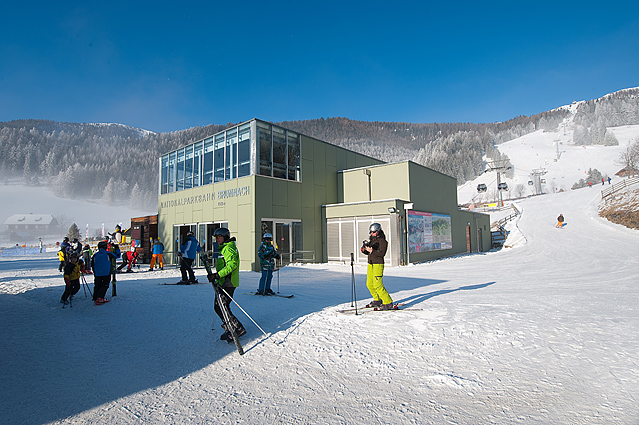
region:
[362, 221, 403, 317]
Person in yellow and black ski gear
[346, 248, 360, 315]
Ski poles stuck in snow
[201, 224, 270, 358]
Person in lime green winter coat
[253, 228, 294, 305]
Person using skis and ski poles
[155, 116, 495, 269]
Light grey ski lodge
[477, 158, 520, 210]
Ski lift in background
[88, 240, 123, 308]
Person in blue jacket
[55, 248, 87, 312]
Person using skis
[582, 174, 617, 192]
Skiiers in background on ski slope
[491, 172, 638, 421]
Long ski slope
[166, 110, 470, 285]
tan building with large windows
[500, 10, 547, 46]
white clouds in blue sky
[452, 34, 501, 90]
white clouds in blue sky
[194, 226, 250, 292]
coat is green in color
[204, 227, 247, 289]
woman is wearing coat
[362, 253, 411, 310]
pants are yellow in color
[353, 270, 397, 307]
person is wearing pants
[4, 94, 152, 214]
trees on the mountain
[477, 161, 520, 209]
ski lift for skiiers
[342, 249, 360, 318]
ski handles for skiier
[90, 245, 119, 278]
coat is blue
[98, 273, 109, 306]
pants are black in color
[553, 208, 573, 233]
person on hill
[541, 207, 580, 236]
A beginner skiing down the bunny slope.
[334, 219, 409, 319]
She is taking a selfie before going skiing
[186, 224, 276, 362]
He is walking towards the ski shop.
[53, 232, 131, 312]
A group of friends getting ready to hit the slope.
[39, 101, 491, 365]
Today ski class is gathering for their class.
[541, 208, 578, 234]
Returning from an early morning ski run.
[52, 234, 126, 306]
The kids are waiting for their parents.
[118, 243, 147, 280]
A beginner about to fall on to the snow.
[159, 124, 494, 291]
tan colored building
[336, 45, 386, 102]
white clouds in blue sky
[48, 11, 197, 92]
Large body of skies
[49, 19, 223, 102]
Large body of skies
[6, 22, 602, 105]
the sky above the mountains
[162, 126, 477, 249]
a tan building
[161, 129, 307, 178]
windows on the building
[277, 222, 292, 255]
the door on the building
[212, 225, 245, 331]
a person in a green jacket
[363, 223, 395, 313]
a person wearing orange ski pants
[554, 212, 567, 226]
a person skiing down the hill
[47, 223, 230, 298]
skiiers standing in front of the snow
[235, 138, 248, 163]
glass is clean and clear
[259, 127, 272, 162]
glass is clean and clear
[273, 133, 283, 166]
glass is clean and clear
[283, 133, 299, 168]
glass is clean and clear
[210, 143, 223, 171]
glass is clean and clear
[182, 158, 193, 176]
glass is clean and clear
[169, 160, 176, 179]
glass is clean and clear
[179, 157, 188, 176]
glass is clean and clear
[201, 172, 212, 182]
glass is clean and clear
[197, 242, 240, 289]
a jacket that is green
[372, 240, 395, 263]
a jacket that is brown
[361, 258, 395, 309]
pants that are yellow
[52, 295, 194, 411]
a shadow that is black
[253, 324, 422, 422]
some snow that is white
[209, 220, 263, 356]
man with black skis in snow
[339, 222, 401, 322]
man with black skis in snow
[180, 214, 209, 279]
man with black skis in snow